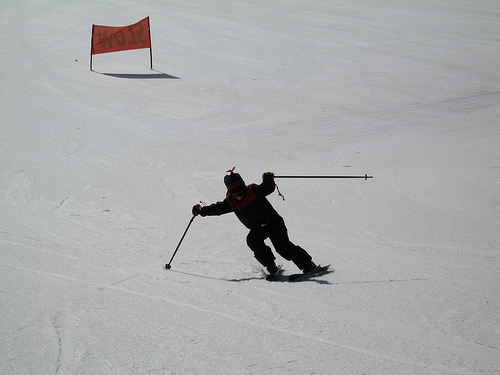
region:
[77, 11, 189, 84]
backwards orange slow sign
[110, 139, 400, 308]
downhill skier with poles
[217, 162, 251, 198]
knitted and striped hat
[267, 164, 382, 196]
ski pole being used by a skier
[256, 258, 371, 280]
downhill skis in the snow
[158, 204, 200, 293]
ski pole poking the snow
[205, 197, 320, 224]
red and black ski sweater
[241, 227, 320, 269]
black ski pants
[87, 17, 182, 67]
orange sign with the word slow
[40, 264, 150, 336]
packed snow with ski tracks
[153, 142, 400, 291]
a skier on a slope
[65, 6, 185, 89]
a sign says slow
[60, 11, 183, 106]
a warning sign on a ski slope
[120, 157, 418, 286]
a skier with two ski poles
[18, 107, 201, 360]
bright white snow on a slope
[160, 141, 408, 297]
a skier dressed in black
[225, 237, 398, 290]
two skis point down hill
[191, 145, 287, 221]
a skier wears a mask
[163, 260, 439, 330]
a skiers shadow on a slope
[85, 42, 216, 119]
the shadow of a sign on a sunny day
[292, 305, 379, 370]
ski tracks in the snow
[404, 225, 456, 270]
2nd set of ski tracks in the snow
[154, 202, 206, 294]
right ski pole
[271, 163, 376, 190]
right ski pole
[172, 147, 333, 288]
person on skis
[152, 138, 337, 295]
person wearing winter gear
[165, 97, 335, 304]
person wearing dark winter gear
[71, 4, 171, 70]
flag marking the ski trail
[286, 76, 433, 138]
snow on a ski slope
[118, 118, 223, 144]
packed down snow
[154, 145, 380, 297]
a young skier on the slope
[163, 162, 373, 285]
the child is holding ski poles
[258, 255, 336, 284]
the skier has short skis on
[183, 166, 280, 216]
the skier is wearing ski gloves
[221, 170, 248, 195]
the child is wearing a knit hat over his helmet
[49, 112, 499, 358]
the slope is well groomed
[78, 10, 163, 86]
a sign in the snow says SLOW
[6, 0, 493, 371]
the gradual slope is the bunny slope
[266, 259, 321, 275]
the boy is wearing ski boots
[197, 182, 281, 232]
the boy is wearing a down jacket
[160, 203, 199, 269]
a stick held by a person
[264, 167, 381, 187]
a stick held by a person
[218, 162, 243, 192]
a black hat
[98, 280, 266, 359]
some marking on ice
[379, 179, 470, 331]
some white ice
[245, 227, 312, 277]
a pair of black pants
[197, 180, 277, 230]
a black jacket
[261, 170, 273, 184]
a black glove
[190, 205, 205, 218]
a black glove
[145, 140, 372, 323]
a person skating